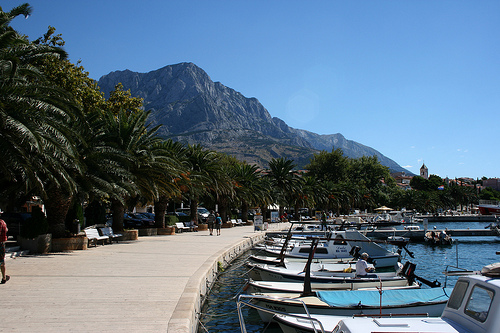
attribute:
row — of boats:
[239, 219, 499, 332]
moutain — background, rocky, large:
[94, 61, 420, 180]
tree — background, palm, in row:
[261, 157, 306, 223]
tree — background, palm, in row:
[145, 137, 195, 228]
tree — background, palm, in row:
[177, 144, 223, 225]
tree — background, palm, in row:
[0, 3, 87, 211]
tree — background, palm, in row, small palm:
[43, 109, 142, 238]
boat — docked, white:
[237, 238, 500, 332]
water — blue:
[198, 220, 500, 332]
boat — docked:
[249, 286, 454, 328]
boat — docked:
[245, 261, 441, 296]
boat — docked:
[245, 222, 377, 268]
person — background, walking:
[215, 212, 222, 236]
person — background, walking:
[206, 209, 216, 237]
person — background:
[318, 209, 329, 232]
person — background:
[0, 208, 10, 284]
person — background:
[356, 251, 377, 278]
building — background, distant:
[394, 163, 445, 189]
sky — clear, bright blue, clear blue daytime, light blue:
[0, 0, 499, 181]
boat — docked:
[246, 249, 403, 281]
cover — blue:
[315, 287, 455, 308]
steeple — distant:
[420, 162, 429, 180]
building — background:
[482, 178, 500, 188]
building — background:
[447, 179, 468, 186]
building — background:
[474, 183, 487, 190]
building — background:
[290, 169, 312, 176]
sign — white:
[253, 214, 263, 227]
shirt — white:
[355, 259, 369, 276]